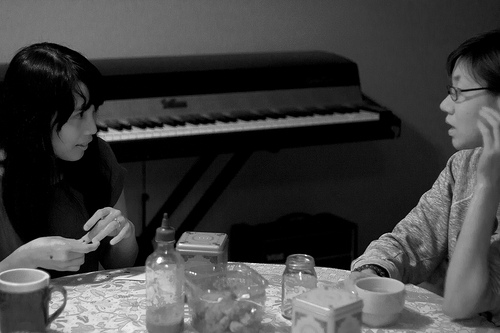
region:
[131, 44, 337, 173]
a black piano on the table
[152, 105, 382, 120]
the keys are black in colour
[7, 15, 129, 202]
the hair is black in colour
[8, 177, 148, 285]
she has a ring on the fingers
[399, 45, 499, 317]
the woman has spectacles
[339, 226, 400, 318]
she has beads on her wrist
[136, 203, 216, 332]
the bottle has a teat pippete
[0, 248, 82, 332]
the cup has a white brim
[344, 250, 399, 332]
the cup has white colour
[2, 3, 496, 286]
the ladies are in a discussion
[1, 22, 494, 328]
women talking across round table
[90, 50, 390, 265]
keyboard on supporting structure against wall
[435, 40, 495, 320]
hand above bent elbow on table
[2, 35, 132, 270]
woman with dark outfit touching fingers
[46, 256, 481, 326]
tablecloth covered with animal figures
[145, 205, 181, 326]
plastic bottle with pointy cap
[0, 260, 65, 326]
dark mug with lighter border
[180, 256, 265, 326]
plastic bag containing fruit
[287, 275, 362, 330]
metal canister with lid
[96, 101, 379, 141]
short black keys above white keys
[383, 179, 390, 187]
part of a wall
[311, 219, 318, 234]
section of a wall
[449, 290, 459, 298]
part of an arm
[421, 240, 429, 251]
part of a sweater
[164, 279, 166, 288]
part of a bottle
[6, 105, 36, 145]
hair of a lady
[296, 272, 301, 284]
part of a tin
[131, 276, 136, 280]
edge of a table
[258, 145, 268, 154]
part of a board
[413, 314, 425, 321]
part of a table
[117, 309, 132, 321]
edge of a table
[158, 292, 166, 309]
part of a bottle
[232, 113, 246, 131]
part of a board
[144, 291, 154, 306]
edge of a bottle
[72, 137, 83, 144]
face of a girl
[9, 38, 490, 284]
people sitting at table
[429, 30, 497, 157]
person wearing glasses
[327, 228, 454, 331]
hand holding coffee cup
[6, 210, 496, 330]
round table with cups on top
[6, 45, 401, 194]
electric piano keyboard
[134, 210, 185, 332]
glass jar with top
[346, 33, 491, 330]
woman wearing long sleeve sweatshirt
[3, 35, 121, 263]
woman with long dark hair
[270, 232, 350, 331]
empty glass jar on table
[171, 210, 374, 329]
metal boxes on table